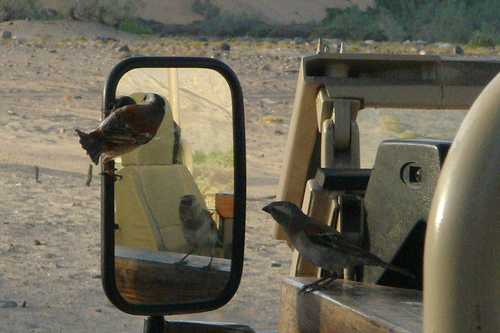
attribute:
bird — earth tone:
[279, 196, 429, 307]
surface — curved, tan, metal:
[421, 70, 499, 332]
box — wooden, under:
[275, 275, 427, 331]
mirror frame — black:
[100, 55, 247, 318]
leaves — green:
[354, 7, 414, 31]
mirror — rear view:
[95, 58, 260, 315]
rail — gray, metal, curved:
[418, 70, 498, 328]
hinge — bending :
[321, 101, 363, 196]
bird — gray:
[76, 76, 191, 194]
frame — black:
[99, 53, 246, 317]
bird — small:
[261, 197, 418, 297]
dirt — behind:
[5, 190, 90, 329]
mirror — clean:
[175, 81, 207, 148]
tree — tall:
[315, 3, 372, 38]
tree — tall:
[368, 7, 404, 42]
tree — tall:
[405, 0, 430, 39]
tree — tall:
[431, 0, 443, 44]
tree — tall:
[453, 0, 468, 45]